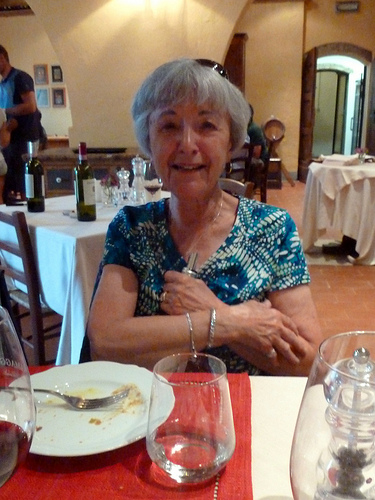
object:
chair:
[2, 212, 46, 365]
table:
[0, 154, 167, 239]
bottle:
[21, 135, 46, 212]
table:
[300, 146, 373, 261]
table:
[5, 177, 105, 313]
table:
[9, 357, 369, 493]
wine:
[143, 183, 159, 191]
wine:
[73, 141, 98, 219]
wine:
[24, 138, 45, 212]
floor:
[1, 178, 374, 373]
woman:
[86, 47, 335, 392]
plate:
[0, 359, 176, 457]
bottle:
[68, 141, 100, 224]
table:
[0, 190, 166, 353]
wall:
[77, 28, 109, 96]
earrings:
[223, 158, 234, 175]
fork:
[3, 380, 131, 411]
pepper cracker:
[312, 346, 374, 499]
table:
[0, 364, 374, 498]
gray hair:
[128, 57, 253, 162]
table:
[297, 149, 372, 270]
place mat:
[0, 362, 252, 497]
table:
[254, 373, 374, 495]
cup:
[145, 348, 238, 485]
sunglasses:
[194, 58, 228, 82]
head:
[131, 59, 250, 204]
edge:
[150, 349, 228, 387]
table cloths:
[301, 150, 373, 264]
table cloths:
[5, 176, 155, 346]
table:
[29, 137, 140, 192]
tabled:
[252, 380, 288, 438]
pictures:
[31, 63, 69, 111]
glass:
[0, 302, 374, 499]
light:
[326, 278, 332, 290]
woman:
[78, 58, 324, 370]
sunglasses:
[190, 57, 231, 81]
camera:
[3, 3, 372, 496]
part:
[324, 168, 337, 183]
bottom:
[163, 470, 221, 491]